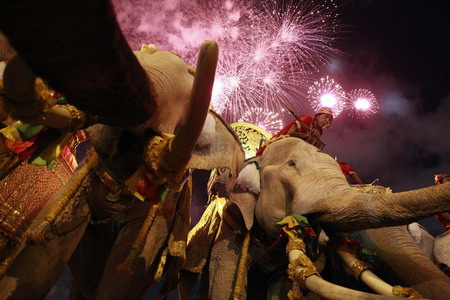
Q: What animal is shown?
A: Elephants.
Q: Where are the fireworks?
A: In the sky.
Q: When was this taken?
A: During the night.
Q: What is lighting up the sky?
A: Fireworks.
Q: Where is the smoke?
A: In the sky.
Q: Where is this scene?
A: It is outside.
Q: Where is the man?
A: Riding the elephant.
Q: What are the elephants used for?
A: Transportation.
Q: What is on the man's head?
A: Hat.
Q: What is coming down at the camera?
A: Elephant's trunk.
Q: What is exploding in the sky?
A: Fireworks.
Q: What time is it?
A: Night.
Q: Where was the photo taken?
A: Outside somewhere.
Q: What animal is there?
A: Elephant.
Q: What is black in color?
A: Sky.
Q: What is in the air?
A: Fireworks.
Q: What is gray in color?
A: The elephant.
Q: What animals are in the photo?
A: Elephants.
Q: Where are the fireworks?
A: In sky.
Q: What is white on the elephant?
A: Tusks.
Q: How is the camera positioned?
A: Facing upwards.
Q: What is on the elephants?
A: Blankets.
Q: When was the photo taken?
A: In the nighttime.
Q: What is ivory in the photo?
A: Tusks.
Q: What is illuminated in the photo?
A: Fireworks.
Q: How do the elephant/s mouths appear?
A: Open.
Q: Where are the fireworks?
A: In the sky.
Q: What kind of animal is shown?
A: Elephant.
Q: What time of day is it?
A: Night time.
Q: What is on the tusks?
A: Decorations.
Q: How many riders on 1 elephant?
A: One.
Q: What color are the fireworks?
A: White.